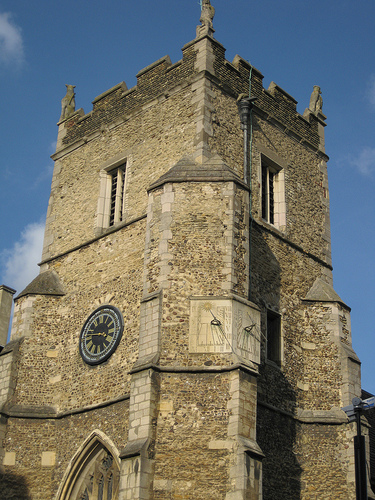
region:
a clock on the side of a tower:
[79, 304, 122, 363]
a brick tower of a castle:
[0, 0, 360, 498]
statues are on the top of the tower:
[59, 84, 77, 118]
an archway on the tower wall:
[54, 428, 119, 497]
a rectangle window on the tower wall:
[260, 152, 285, 231]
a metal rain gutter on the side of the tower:
[237, 92, 255, 184]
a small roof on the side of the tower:
[146, 155, 251, 192]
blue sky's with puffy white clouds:
[1, 0, 41, 279]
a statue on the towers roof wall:
[195, 0, 214, 39]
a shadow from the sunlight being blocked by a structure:
[256, 359, 303, 498]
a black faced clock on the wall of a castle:
[79, 305, 122, 364]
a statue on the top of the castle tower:
[197, 0, 214, 38]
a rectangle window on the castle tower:
[100, 157, 125, 223]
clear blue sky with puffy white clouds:
[0, 1, 36, 282]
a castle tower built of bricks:
[0, 0, 366, 499]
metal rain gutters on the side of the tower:
[237, 92, 252, 219]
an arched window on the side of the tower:
[55, 430, 118, 499]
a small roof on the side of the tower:
[14, 270, 65, 296]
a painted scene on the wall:
[243, 451, 261, 498]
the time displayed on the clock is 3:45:
[79, 305, 120, 361]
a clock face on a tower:
[60, 290, 137, 387]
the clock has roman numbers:
[44, 284, 163, 364]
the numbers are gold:
[64, 294, 154, 393]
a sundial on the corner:
[176, 281, 287, 382]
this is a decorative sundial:
[169, 287, 321, 420]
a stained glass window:
[32, 414, 160, 498]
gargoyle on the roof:
[28, 28, 118, 168]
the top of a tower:
[30, 22, 361, 216]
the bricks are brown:
[173, 385, 246, 445]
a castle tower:
[37, 25, 356, 271]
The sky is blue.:
[19, 15, 100, 77]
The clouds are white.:
[1, 191, 47, 297]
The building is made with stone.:
[167, 385, 226, 480]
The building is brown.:
[115, 259, 267, 489]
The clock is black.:
[60, 292, 135, 375]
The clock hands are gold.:
[72, 294, 120, 371]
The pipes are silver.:
[228, 26, 264, 204]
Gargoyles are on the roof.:
[47, 64, 87, 122]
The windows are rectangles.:
[93, 141, 140, 233]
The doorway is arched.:
[29, 387, 116, 494]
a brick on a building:
[133, 375, 145, 386]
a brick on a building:
[133, 393, 143, 400]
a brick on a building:
[137, 383, 152, 392]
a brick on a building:
[138, 399, 152, 407]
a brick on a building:
[133, 410, 143, 414]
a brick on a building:
[139, 415, 151, 423]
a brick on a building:
[139, 424, 150, 439]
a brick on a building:
[132, 454, 150, 472]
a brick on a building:
[129, 471, 146, 486]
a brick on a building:
[119, 456, 131, 476]